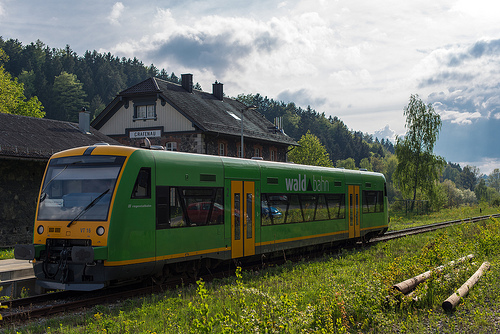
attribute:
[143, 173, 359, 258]
train — green, yellow, moving, rural, here, passenger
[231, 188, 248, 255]
doors — yellow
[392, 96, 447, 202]
tree — tall, green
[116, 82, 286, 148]
building — brown, background, here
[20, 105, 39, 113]
weed — green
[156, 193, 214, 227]
window — square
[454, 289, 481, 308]
pole — light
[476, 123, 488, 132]
sky — shiny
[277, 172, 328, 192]
writing — white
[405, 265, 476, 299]
logs — brown, here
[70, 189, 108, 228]
wiper — black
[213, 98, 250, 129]
roof — black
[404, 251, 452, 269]
plants — small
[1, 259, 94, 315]
railroad — here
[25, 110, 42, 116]
wildflowers — here